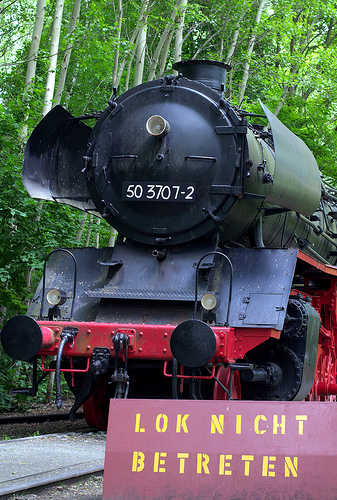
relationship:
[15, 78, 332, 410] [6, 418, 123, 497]
train on tracks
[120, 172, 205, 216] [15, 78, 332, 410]
number on train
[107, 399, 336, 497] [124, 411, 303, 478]
sign has lettering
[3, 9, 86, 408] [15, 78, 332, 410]
trees behind train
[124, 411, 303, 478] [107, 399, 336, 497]
lettering on sign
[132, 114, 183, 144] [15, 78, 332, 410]
light on train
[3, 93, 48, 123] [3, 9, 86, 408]
leaves on trees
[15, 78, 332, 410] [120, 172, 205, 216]
train has number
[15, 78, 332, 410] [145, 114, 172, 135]
train has light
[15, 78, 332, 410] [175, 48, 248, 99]
train has smokestack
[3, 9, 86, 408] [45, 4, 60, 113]
trees have trunk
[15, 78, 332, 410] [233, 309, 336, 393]
train has engine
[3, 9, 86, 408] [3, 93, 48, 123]
trees have leaves